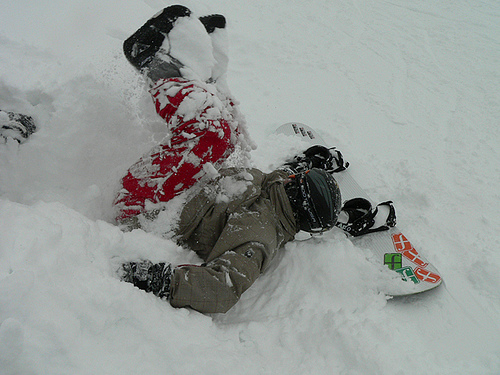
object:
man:
[117, 3, 346, 313]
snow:
[47, 314, 132, 360]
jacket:
[170, 167, 287, 313]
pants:
[116, 81, 237, 217]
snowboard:
[275, 114, 446, 299]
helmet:
[286, 167, 342, 236]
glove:
[115, 260, 174, 292]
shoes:
[120, 6, 190, 65]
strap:
[329, 197, 399, 241]